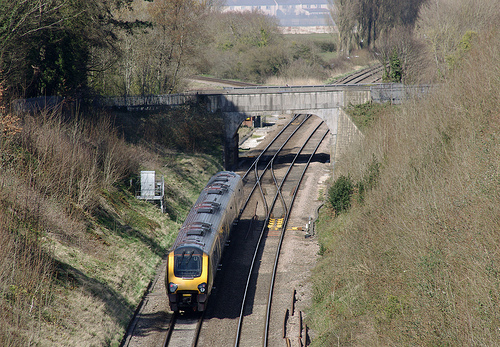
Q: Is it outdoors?
A: Yes, it is outdoors.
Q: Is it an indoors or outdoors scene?
A: It is outdoors.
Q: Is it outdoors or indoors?
A: It is outdoors.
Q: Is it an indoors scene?
A: No, it is outdoors.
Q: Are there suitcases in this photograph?
A: No, there are no suitcases.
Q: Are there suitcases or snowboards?
A: No, there are no suitcases or snowboards.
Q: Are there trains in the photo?
A: Yes, there is a train.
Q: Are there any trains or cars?
A: Yes, there is a train.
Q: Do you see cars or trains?
A: Yes, there is a train.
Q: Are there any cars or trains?
A: Yes, there is a train.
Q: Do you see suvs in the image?
A: No, there are no suvs.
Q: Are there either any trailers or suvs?
A: No, there are no suvs or trailers.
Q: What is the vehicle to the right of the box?
A: The vehicle is a train.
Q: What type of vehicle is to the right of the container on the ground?
A: The vehicle is a train.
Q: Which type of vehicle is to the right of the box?
A: The vehicle is a train.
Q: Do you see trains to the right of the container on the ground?
A: Yes, there is a train to the right of the box.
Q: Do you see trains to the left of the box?
A: No, the train is to the right of the box.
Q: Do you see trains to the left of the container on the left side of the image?
A: No, the train is to the right of the box.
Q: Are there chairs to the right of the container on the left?
A: No, there is a train to the right of the box.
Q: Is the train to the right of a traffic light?
A: No, the train is to the right of the box.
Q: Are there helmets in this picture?
A: No, there are no helmets.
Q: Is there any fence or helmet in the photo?
A: No, there are no helmets or fences.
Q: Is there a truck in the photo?
A: No, there are no trucks.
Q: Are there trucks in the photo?
A: No, there are no trucks.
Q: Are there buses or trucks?
A: No, there are no trucks or buses.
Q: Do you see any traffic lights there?
A: No, there are no traffic lights.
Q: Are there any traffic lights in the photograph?
A: No, there are no traffic lights.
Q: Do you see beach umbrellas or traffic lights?
A: No, there are no traffic lights or beach umbrellas.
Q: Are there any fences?
A: No, there are no fences.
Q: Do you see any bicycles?
A: No, there are no bicycles.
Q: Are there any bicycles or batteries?
A: No, there are no bicycles or batteries.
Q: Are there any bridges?
A: Yes, there is a bridge.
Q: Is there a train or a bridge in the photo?
A: Yes, there is a bridge.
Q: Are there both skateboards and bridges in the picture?
A: No, there is a bridge but no skateboards.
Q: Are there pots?
A: No, there are no pots.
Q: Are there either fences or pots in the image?
A: No, there are no pots or fences.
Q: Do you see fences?
A: No, there are no fences.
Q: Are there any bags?
A: No, there are no bags.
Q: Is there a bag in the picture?
A: No, there are no bags.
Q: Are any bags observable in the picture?
A: No, there are no bags.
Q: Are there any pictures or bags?
A: No, there are no bags or pictures.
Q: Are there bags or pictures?
A: No, there are no bags or pictures.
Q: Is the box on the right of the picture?
A: No, the box is on the left of the image.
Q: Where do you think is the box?
A: The box is on the ground.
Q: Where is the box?
A: The box is on the ground.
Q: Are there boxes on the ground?
A: Yes, there is a box on the ground.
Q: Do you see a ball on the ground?
A: No, there is a box on the ground.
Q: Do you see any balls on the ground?
A: No, there is a box on the ground.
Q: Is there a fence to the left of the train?
A: No, there is a box to the left of the train.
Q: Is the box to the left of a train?
A: Yes, the box is to the left of a train.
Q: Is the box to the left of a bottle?
A: No, the box is to the left of a train.